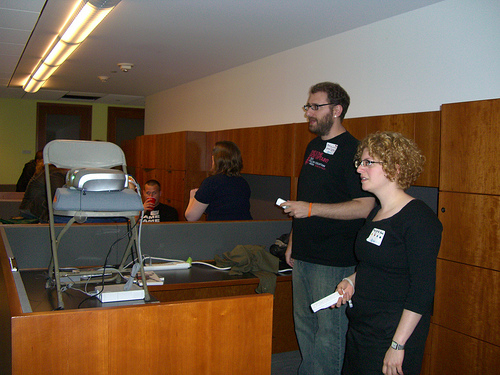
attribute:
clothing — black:
[343, 218, 423, 374]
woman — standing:
[349, 132, 445, 374]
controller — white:
[305, 290, 349, 319]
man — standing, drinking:
[300, 68, 363, 350]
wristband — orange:
[303, 200, 320, 225]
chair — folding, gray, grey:
[37, 143, 149, 264]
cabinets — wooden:
[134, 130, 202, 209]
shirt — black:
[297, 146, 365, 263]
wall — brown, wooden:
[153, 115, 294, 183]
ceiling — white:
[119, 13, 255, 67]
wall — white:
[183, 10, 470, 118]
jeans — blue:
[279, 259, 352, 374]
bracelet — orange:
[300, 196, 325, 221]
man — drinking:
[134, 156, 175, 235]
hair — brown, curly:
[384, 138, 420, 185]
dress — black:
[352, 205, 427, 371]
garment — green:
[221, 243, 278, 295]